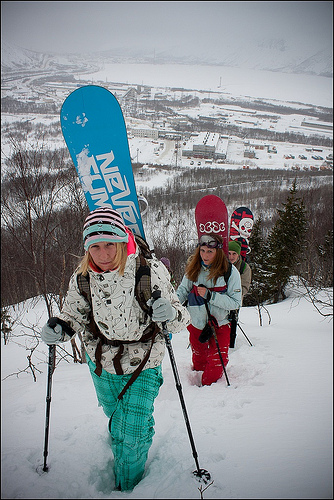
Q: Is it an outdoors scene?
A: Yes, it is outdoors.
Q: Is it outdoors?
A: Yes, it is outdoors.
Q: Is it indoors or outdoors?
A: It is outdoors.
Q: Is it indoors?
A: No, it is outdoors.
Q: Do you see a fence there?
A: No, there are no fences.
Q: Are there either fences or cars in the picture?
A: No, there are no fences or cars.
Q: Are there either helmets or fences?
A: No, there are no fences or helmets.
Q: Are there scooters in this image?
A: No, there are no scooters.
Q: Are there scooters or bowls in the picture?
A: No, there are no scooters or bowls.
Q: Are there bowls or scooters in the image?
A: No, there are no scooters or bowls.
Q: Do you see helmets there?
A: No, there are no helmets.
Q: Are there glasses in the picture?
A: No, there are no glasses.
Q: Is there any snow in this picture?
A: Yes, there is snow.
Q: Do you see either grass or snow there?
A: Yes, there is snow.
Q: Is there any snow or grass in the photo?
A: Yes, there is snow.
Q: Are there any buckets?
A: No, there are no buckets.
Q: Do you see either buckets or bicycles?
A: No, there are no buckets or bicycles.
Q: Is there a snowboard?
A: Yes, there is a snowboard.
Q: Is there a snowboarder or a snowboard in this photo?
A: Yes, there is a snowboard.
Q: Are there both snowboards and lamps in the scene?
A: No, there is a snowboard but no lamps.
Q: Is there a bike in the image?
A: No, there are no bikes.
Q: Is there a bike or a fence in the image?
A: No, there are no bikes or fences.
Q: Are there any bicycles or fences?
A: No, there are no bicycles or fences.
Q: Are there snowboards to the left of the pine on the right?
A: Yes, there is a snowboard to the left of the pine tree.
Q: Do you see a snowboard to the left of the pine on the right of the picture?
A: Yes, there is a snowboard to the left of the pine tree.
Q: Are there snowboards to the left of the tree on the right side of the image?
A: Yes, there is a snowboard to the left of the pine tree.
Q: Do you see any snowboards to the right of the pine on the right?
A: No, the snowboard is to the left of the pine tree.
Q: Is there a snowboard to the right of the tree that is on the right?
A: No, the snowboard is to the left of the pine tree.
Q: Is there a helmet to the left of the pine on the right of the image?
A: No, there is a snowboard to the left of the pine tree.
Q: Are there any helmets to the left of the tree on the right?
A: No, there is a snowboard to the left of the pine tree.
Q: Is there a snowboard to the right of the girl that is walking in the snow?
A: Yes, there is a snowboard to the right of the girl.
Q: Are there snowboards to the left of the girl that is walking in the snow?
A: No, the snowboard is to the right of the girl.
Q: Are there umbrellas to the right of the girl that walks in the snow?
A: No, there is a snowboard to the right of the girl.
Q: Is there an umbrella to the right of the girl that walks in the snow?
A: No, there is a snowboard to the right of the girl.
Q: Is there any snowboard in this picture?
A: Yes, there is a snowboard.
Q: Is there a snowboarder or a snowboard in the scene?
A: Yes, there is a snowboard.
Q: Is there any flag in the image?
A: No, there are no flags.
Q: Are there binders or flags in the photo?
A: No, there are no flags or binders.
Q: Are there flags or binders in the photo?
A: No, there are no flags or binders.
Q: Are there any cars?
A: No, there are no cars.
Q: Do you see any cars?
A: No, there are no cars.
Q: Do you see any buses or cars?
A: No, there are no cars or buses.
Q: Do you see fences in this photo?
A: No, there are no fences.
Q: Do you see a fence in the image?
A: No, there are no fences.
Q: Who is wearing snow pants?
A: The girl is wearing snow pants.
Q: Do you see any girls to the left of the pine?
A: Yes, there is a girl to the left of the pine.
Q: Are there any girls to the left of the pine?
A: Yes, there is a girl to the left of the pine.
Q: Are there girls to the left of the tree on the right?
A: Yes, there is a girl to the left of the pine.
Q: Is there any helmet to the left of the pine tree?
A: No, there is a girl to the left of the pine tree.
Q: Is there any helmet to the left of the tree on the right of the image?
A: No, there is a girl to the left of the pine tree.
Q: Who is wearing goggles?
A: The girl is wearing goggles.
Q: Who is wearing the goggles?
A: The girl is wearing goggles.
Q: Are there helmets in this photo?
A: No, there are no helmets.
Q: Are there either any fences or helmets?
A: No, there are no helmets or fences.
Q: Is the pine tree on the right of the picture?
A: Yes, the pine tree is on the right of the image.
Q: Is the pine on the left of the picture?
A: No, the pine is on the right of the image.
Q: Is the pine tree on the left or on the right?
A: The pine tree is on the right of the image.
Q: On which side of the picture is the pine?
A: The pine is on the right of the image.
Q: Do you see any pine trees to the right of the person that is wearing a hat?
A: Yes, there is a pine tree to the right of the person.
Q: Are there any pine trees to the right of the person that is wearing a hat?
A: Yes, there is a pine tree to the right of the person.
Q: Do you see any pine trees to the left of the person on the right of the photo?
A: No, the pine tree is to the right of the person.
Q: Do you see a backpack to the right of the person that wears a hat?
A: No, there is a pine tree to the right of the person.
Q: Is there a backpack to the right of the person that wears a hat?
A: No, there is a pine tree to the right of the person.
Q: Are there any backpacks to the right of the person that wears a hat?
A: No, there is a pine tree to the right of the person.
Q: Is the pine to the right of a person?
A: Yes, the pine is to the right of a person.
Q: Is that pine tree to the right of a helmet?
A: No, the pine tree is to the right of a person.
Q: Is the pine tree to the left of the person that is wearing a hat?
A: No, the pine tree is to the right of the person.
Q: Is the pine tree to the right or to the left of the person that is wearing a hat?
A: The pine tree is to the right of the person.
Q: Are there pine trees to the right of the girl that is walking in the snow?
A: Yes, there is a pine tree to the right of the girl.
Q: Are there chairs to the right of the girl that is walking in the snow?
A: No, there is a pine tree to the right of the girl.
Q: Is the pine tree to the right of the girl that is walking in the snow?
A: Yes, the pine tree is to the right of the girl.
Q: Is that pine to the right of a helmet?
A: No, the pine is to the right of the girl.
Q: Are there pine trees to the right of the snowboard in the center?
A: Yes, there is a pine tree to the right of the snowboard.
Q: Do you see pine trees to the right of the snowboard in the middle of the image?
A: Yes, there is a pine tree to the right of the snowboard.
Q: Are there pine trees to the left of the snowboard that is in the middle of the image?
A: No, the pine tree is to the right of the snowboard.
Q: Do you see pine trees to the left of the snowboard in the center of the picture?
A: No, the pine tree is to the right of the snowboard.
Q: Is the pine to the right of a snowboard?
A: Yes, the pine is to the right of a snowboard.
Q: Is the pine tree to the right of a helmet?
A: No, the pine tree is to the right of a snowboard.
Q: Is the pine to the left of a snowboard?
A: No, the pine is to the right of a snowboard.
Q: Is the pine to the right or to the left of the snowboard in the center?
A: The pine is to the right of the snowboard.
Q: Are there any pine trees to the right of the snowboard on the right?
A: Yes, there is a pine tree to the right of the snow board.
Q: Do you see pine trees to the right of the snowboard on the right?
A: Yes, there is a pine tree to the right of the snow board.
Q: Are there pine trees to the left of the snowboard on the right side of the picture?
A: No, the pine tree is to the right of the snowboard.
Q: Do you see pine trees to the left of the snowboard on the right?
A: No, the pine tree is to the right of the snowboard.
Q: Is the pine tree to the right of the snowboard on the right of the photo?
A: Yes, the pine tree is to the right of the snow board.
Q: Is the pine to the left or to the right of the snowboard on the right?
A: The pine is to the right of the snow board.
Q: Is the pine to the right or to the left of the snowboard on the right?
A: The pine is to the right of the snow board.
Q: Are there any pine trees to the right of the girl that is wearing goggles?
A: Yes, there is a pine tree to the right of the girl.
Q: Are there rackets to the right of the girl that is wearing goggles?
A: No, there is a pine tree to the right of the girl.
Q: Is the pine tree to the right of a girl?
A: Yes, the pine tree is to the right of a girl.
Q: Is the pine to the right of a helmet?
A: No, the pine is to the right of a girl.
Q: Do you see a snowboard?
A: Yes, there is a snowboard.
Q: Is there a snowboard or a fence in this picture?
A: Yes, there is a snowboard.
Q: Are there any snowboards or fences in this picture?
A: Yes, there is a snowboard.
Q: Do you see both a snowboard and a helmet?
A: No, there is a snowboard but no helmets.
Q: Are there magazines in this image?
A: No, there are no magazines.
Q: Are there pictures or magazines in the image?
A: No, there are no magazines or pictures.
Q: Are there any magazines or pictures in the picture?
A: No, there are no magazines or pictures.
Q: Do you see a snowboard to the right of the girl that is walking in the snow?
A: Yes, there is a snowboard to the right of the girl.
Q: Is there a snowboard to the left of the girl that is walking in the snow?
A: No, the snowboard is to the right of the girl.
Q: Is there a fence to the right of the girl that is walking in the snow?
A: No, there is a snowboard to the right of the girl.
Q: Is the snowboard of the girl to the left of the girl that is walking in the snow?
A: No, the snowboard is to the right of the girl.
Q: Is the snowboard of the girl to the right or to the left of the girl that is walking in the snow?
A: The snowboard is to the right of the girl.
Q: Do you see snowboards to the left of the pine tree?
A: Yes, there is a snowboard to the left of the pine tree.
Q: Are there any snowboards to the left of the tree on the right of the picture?
A: Yes, there is a snowboard to the left of the pine tree.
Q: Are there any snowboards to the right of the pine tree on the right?
A: No, the snowboard is to the left of the pine tree.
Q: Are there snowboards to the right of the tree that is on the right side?
A: No, the snowboard is to the left of the pine tree.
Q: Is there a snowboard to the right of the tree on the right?
A: No, the snowboard is to the left of the pine tree.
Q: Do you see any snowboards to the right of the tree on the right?
A: No, the snowboard is to the left of the pine tree.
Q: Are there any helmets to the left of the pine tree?
A: No, there is a snowboard to the left of the pine tree.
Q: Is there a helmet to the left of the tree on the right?
A: No, there is a snowboard to the left of the pine tree.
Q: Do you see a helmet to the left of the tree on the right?
A: No, there is a snowboard to the left of the pine tree.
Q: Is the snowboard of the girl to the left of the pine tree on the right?
A: Yes, the snowboard is to the left of the pine tree.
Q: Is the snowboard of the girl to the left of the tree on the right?
A: Yes, the snowboard is to the left of the pine tree.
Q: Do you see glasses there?
A: No, there are no glasses.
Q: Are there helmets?
A: No, there are no helmets.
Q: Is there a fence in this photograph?
A: No, there are no fences.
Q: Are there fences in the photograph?
A: No, there are no fences.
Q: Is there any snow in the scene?
A: Yes, there is snow.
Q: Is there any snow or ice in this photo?
A: Yes, there is snow.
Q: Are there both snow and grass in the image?
A: No, there is snow but no grass.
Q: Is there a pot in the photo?
A: No, there are no pots.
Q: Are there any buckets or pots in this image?
A: No, there are no pots or buckets.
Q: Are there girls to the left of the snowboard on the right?
A: Yes, there is a girl to the left of the snowboard.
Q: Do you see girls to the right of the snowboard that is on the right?
A: No, the girl is to the left of the snow board.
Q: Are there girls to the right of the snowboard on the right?
A: No, the girl is to the left of the snow board.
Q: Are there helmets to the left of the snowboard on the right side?
A: No, there is a girl to the left of the snowboard.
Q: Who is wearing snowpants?
A: The girl is wearing snowpants.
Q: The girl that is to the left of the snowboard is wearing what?
A: The girl is wearing snow pants.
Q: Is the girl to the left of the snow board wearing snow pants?
A: Yes, the girl is wearing snow pants.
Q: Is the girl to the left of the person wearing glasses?
A: No, the girl is wearing snow pants.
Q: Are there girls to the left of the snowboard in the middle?
A: Yes, there is a girl to the left of the snowboard.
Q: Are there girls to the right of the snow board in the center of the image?
A: No, the girl is to the left of the snow board.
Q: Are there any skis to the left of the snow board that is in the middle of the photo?
A: No, there is a girl to the left of the snowboard.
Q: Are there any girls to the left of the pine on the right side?
A: Yes, there is a girl to the left of the pine.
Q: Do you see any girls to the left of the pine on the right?
A: Yes, there is a girl to the left of the pine.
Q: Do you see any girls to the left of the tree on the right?
A: Yes, there is a girl to the left of the pine.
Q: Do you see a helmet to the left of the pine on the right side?
A: No, there is a girl to the left of the pine.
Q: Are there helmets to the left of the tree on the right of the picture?
A: No, there is a girl to the left of the pine.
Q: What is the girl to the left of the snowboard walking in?
A: The girl is walking in the snow.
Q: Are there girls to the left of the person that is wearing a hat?
A: Yes, there is a girl to the left of the person.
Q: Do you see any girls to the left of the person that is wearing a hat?
A: Yes, there is a girl to the left of the person.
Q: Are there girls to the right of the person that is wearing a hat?
A: No, the girl is to the left of the person.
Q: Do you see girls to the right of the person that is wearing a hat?
A: No, the girl is to the left of the person.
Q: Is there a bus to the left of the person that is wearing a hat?
A: No, there is a girl to the left of the person.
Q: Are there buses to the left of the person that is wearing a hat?
A: No, there is a girl to the left of the person.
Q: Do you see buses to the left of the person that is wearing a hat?
A: No, there is a girl to the left of the person.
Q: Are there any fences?
A: No, there are no fences.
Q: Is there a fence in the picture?
A: No, there are no fences.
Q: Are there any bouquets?
A: No, there are no bouquets.